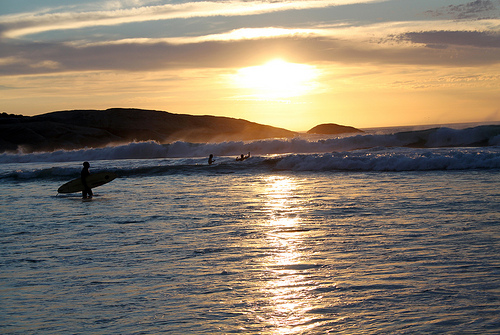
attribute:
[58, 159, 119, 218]
person — one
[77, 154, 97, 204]
man — surfboard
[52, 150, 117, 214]
man — water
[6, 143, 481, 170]
wave — large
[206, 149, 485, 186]
wave — smaller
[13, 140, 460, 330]
water — shallow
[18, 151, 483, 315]
water — calm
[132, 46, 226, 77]
cloud — grey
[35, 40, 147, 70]
cloud — grey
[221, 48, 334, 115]
sun — yellow